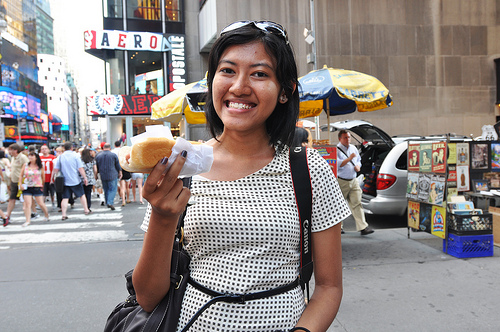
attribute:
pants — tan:
[340, 175, 370, 231]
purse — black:
[102, 144, 206, 330]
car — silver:
[327, 115, 464, 224]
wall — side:
[215, 3, 498, 135]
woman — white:
[19, 146, 55, 228]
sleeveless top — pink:
[21, 164, 44, 187]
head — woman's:
[191, 22, 313, 129]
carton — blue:
[447, 236, 492, 253]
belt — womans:
[175, 286, 292, 306]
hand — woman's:
[119, 157, 216, 228]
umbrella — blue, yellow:
[298, 56, 418, 153]